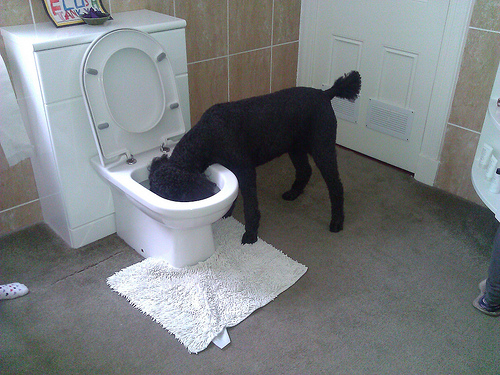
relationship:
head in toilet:
[146, 148, 212, 202] [43, 16, 265, 286]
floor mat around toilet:
[105, 213, 307, 354] [73, 19, 243, 272]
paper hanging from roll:
[0, 58, 35, 167] [0, 60, 15, 90]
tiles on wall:
[187, 5, 294, 89] [0, 0, 307, 246]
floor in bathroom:
[0, 144, 499, 374] [1, 2, 498, 372]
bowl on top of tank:
[82, 11, 114, 27] [0, 8, 192, 249]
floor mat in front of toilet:
[103, 213, 310, 357] [50, 3, 239, 261]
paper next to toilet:
[2, 62, 37, 173] [73, 19, 243, 272]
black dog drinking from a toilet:
[148, 71, 361, 244] [73, 19, 243, 272]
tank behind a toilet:
[0, 8, 192, 249] [78, 29, 239, 266]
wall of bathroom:
[0, 0, 307, 246] [1, 2, 498, 372]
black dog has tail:
[148, 71, 361, 244] [324, 63, 363, 104]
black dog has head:
[148, 71, 361, 244] [146, 156, 212, 203]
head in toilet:
[146, 156, 212, 203] [78, 29, 239, 266]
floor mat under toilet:
[105, 213, 307, 354] [73, 19, 243, 272]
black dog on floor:
[148, 71, 361, 244] [372, 162, 494, 368]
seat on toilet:
[80, 25, 193, 164] [78, 29, 239, 266]